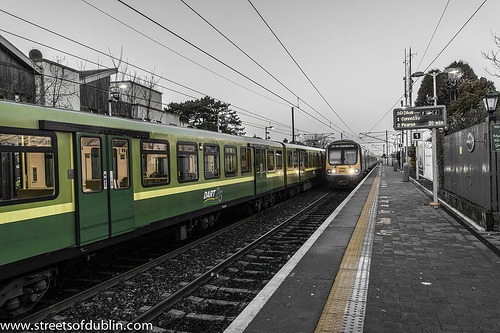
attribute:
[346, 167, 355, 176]
headlight — turned on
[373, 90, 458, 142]
train sign — black , yellow 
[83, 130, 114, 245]
door — dark green, black, train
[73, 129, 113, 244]
train door — dark green, black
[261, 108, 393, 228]
train — yellow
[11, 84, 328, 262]
train — long, dark green, light green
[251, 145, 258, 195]
train door — dark , green , black 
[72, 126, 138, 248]
doors — double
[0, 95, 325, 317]
train — green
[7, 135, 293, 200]
lights — on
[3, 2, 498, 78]
electric lines — above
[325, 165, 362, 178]
light — on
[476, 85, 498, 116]
streetlight — off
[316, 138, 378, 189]
train — green, yellow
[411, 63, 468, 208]
post — street light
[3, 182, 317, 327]
tracks — railroad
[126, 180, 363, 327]
tracks — railroad